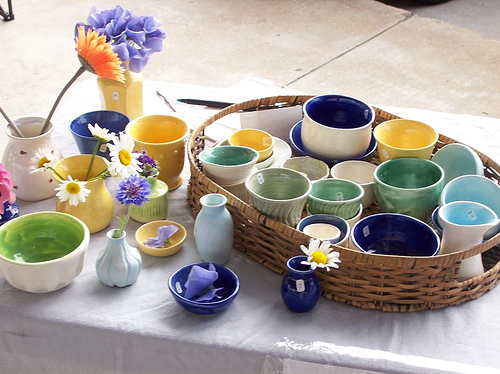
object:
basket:
[187, 94, 500, 313]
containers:
[371, 118, 439, 165]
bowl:
[0, 210, 90, 295]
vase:
[93, 228, 144, 289]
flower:
[114, 175, 152, 206]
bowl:
[131, 218, 188, 258]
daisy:
[298, 238, 343, 273]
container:
[279, 255, 321, 313]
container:
[50, 153, 113, 235]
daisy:
[26, 146, 57, 174]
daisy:
[106, 131, 145, 179]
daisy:
[84, 122, 117, 145]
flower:
[135, 151, 160, 177]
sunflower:
[73, 25, 129, 84]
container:
[122, 114, 189, 192]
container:
[227, 128, 274, 163]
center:
[309, 250, 327, 266]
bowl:
[165, 261, 242, 316]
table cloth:
[0, 82, 499, 372]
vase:
[193, 193, 236, 267]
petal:
[166, 222, 178, 238]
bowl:
[304, 177, 366, 220]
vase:
[1, 115, 66, 202]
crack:
[279, 10, 414, 89]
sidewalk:
[0, 0, 499, 119]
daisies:
[51, 175, 90, 207]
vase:
[373, 156, 445, 225]